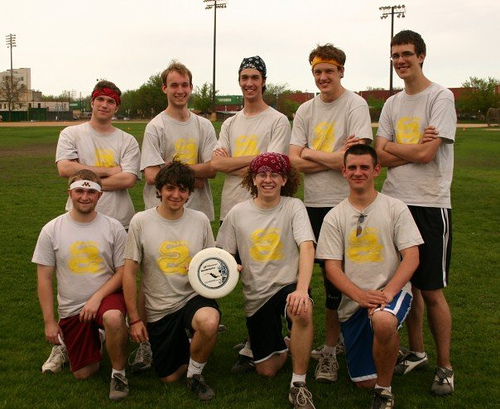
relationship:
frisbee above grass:
[181, 241, 243, 300] [459, 172, 493, 366]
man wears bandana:
[214, 148, 321, 407] [249, 150, 291, 175]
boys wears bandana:
[313, 143, 425, 409] [249, 150, 291, 175]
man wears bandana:
[121, 152, 242, 400] [238, 53, 263, 78]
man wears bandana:
[26, 163, 135, 400] [238, 53, 263, 78]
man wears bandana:
[51, 79, 144, 232] [238, 53, 263, 78]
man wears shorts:
[26, 163, 135, 400] [47, 291, 127, 372]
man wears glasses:
[373, 29, 459, 396] [388, 50, 416, 59]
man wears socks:
[118, 151, 227, 400] [193, 358, 209, 372]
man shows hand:
[214, 148, 321, 407] [286, 290, 309, 315]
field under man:
[2, 126, 499, 403] [215, 151, 319, 409]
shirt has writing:
[213, 149, 316, 407] [245, 226, 287, 263]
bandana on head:
[249, 151, 292, 175] [378, 23, 426, 93]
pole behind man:
[212, 0, 217, 112] [215, 151, 319, 409]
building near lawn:
[1, 63, 77, 124] [6, 118, 56, 197]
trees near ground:
[124, 80, 158, 112] [6, 121, 61, 215]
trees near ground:
[457, 75, 499, 122] [6, 121, 61, 215]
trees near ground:
[2, 70, 27, 107] [6, 121, 61, 215]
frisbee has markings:
[188, 247, 240, 300] [197, 251, 229, 290]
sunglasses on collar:
[345, 202, 380, 249] [348, 193, 386, 213]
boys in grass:
[318, 142, 422, 407] [2, 119, 498, 406]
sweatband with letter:
[65, 177, 105, 195] [82, 177, 98, 186]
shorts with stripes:
[319, 276, 467, 370] [386, 286, 415, 324]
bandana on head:
[235, 57, 275, 71] [224, 55, 271, 111]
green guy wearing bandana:
[210, 55, 292, 350] [235, 57, 275, 71]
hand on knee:
[283, 287, 313, 316] [267, 267, 322, 407]